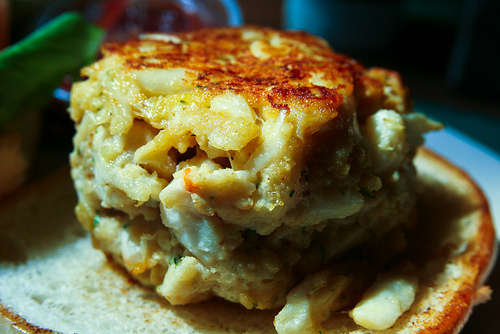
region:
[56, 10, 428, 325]
Crab cake is cooked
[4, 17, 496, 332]
Crab cake is on bread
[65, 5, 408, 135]
Crab cake is brown on top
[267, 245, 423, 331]
Pieces of crab cake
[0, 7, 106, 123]
Green napkin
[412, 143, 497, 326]
Bread is brown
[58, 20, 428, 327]
Crab cake shape is round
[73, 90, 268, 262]
Crab cake has holes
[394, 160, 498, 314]
Shadow of crab cake on bread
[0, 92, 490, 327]
bread under the tortilla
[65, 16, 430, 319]
mexican tortilla food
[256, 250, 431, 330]
onion on the bottom right corner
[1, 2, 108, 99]
green serviette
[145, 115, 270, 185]
melted cheese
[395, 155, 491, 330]
burned part of the bread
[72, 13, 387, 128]
burned part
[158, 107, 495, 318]
blue plate under the bread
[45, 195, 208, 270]
spinach on th ebread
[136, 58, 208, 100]
onion on the top of the tortilla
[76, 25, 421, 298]
the crab cake is large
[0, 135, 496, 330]
the bread is toasted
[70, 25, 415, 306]
the cake has a lot of lumps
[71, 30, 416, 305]
the cake was fried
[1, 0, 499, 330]
the picture is dark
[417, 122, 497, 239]
the plate is white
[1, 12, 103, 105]
the lettuce is green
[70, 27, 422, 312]
the cake is thick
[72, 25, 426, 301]
the crab cake has herbs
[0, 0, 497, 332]
a picture of food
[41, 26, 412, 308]
A food item that has been cooked.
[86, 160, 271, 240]
The center filling of a food item.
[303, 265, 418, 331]
Melted cheese next to a food item.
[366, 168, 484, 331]
A plate with food on top of it.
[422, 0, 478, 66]
Dark area of a room near food.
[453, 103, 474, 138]
Section of a table that food is on.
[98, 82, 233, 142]
Melted cheese on a food item.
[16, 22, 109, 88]
green object in a kitchen.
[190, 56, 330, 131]
burned area of food.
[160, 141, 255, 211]
Red area of food.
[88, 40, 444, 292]
this is some food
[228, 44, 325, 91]
the food is brown in color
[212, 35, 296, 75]
the food is oily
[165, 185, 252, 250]
the part is white in color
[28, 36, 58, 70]
this is a cloth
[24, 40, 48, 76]
the cloth is green in color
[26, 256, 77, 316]
this is some bread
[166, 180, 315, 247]
the food has some spices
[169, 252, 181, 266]
the spices are green in color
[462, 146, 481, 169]
this is a plate